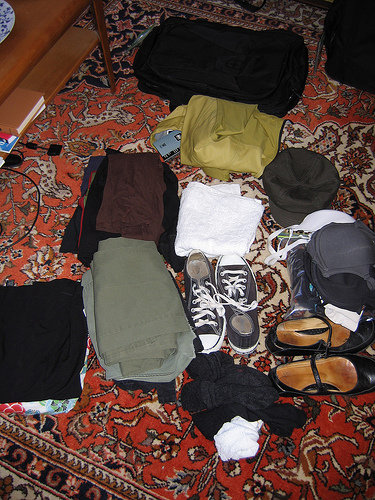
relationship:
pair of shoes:
[183, 251, 260, 354] [183, 249, 260, 355]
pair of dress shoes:
[266, 313, 375, 397] [267, 317, 375, 396]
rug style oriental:
[0, 1, 375, 499] [0, 1, 375, 499]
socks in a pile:
[181, 351, 307, 459] [183, 350, 307, 460]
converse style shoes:
[183, 251, 260, 354] [183, 249, 260, 355]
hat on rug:
[263, 147, 340, 228] [0, 1, 375, 499]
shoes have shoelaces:
[183, 249, 260, 355] [190, 268, 259, 326]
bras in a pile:
[266, 210, 375, 313] [263, 209, 373, 316]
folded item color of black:
[0, 278, 86, 402] [0, 278, 88, 403]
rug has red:
[0, 1, 375, 499] [0, 1, 375, 499]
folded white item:
[174, 178, 263, 261] [174, 179, 265, 259]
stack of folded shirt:
[58, 147, 179, 270] [96, 152, 168, 243]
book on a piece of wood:
[0, 89, 47, 135] [0, 26, 101, 168]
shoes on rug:
[183, 249, 260, 355] [0, 1, 375, 499]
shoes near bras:
[183, 249, 260, 355] [266, 210, 375, 313]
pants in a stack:
[81, 237, 205, 402] [80, 237, 205, 405]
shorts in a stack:
[0, 278, 89, 414] [1, 278, 90, 420]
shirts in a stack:
[59, 148, 178, 269] [58, 147, 179, 270]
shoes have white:
[183, 249, 260, 355] [183, 248, 263, 354]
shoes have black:
[183, 249, 260, 355] [183, 249, 262, 357]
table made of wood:
[0, 0, 117, 169] [1, 0, 116, 169]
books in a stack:
[0, 87, 49, 154] [1, 88, 48, 155]